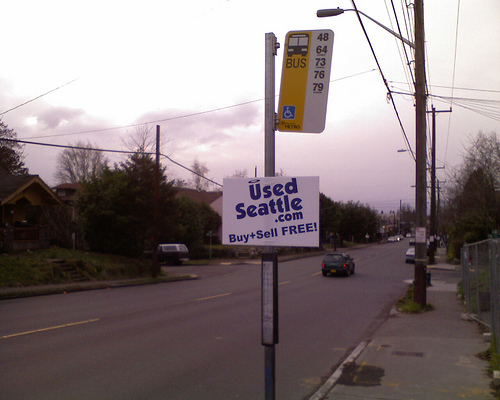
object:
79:
[312, 82, 324, 91]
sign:
[224, 177, 320, 248]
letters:
[248, 182, 263, 201]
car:
[320, 249, 356, 277]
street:
[0, 234, 411, 400]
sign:
[277, 26, 342, 134]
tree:
[78, 146, 171, 259]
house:
[0, 173, 90, 254]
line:
[191, 290, 236, 303]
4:
[316, 32, 324, 41]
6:
[314, 44, 322, 54]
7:
[315, 57, 321, 67]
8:
[323, 33, 329, 41]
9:
[318, 81, 325, 92]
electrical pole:
[412, 3, 430, 305]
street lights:
[313, 5, 419, 49]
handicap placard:
[281, 104, 297, 120]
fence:
[463, 241, 498, 330]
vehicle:
[144, 242, 190, 266]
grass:
[34, 246, 97, 257]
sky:
[2, 4, 489, 184]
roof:
[0, 173, 66, 206]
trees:
[0, 122, 37, 233]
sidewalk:
[324, 257, 500, 399]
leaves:
[130, 186, 137, 191]